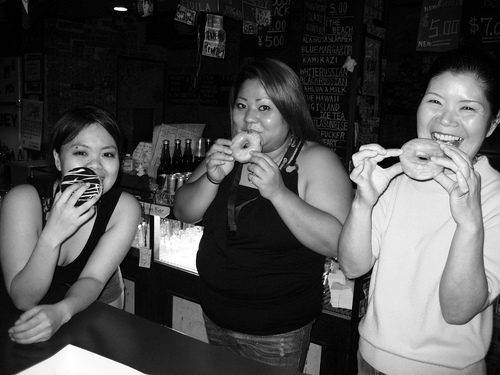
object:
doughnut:
[399, 137, 448, 180]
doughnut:
[230, 131, 262, 163]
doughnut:
[60, 166, 103, 207]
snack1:
[229, 130, 263, 163]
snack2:
[398, 137, 448, 181]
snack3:
[60, 165, 104, 206]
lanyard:
[226, 136, 306, 233]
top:
[28, 182, 124, 291]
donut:
[59, 166, 103, 207]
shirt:
[357, 155, 500, 375]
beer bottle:
[155, 139, 173, 184]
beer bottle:
[170, 138, 183, 174]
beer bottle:
[181, 138, 193, 174]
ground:
[345, 166, 379, 198]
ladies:
[0, 57, 500, 375]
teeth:
[433, 133, 461, 142]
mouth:
[429, 131, 464, 147]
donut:
[38, 166, 103, 245]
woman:
[0, 109, 143, 345]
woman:
[171, 58, 352, 375]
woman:
[337, 63, 500, 375]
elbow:
[337, 212, 373, 278]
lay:
[444, 79, 463, 98]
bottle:
[155, 139, 171, 185]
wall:
[4, 1, 382, 54]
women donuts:
[0, 54, 500, 375]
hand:
[247, 150, 284, 201]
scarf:
[225, 134, 305, 232]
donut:
[398, 137, 448, 180]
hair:
[233, 60, 323, 145]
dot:
[75, 147, 78, 150]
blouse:
[194, 134, 327, 336]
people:
[0, 58, 500, 375]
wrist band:
[198, 166, 225, 190]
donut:
[228, 131, 263, 164]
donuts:
[59, 130, 450, 207]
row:
[158, 171, 193, 195]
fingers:
[430, 143, 474, 196]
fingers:
[349, 144, 404, 185]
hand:
[349, 143, 405, 205]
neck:
[260, 132, 306, 158]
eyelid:
[71, 146, 89, 156]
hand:
[41, 182, 100, 247]